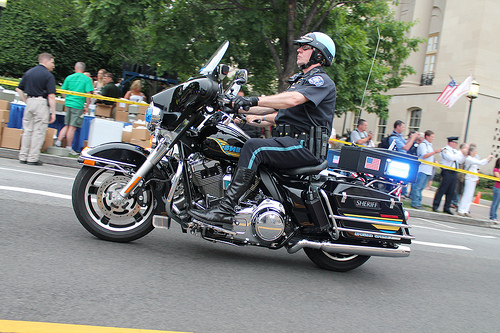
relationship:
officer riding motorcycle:
[183, 27, 343, 231] [68, 27, 416, 275]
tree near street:
[173, 2, 434, 110] [2, 153, 496, 332]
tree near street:
[1, 3, 173, 95] [2, 153, 496, 332]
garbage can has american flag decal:
[334, 140, 391, 181] [363, 155, 382, 171]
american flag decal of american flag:
[363, 155, 382, 171] [359, 153, 385, 178]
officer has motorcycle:
[183, 27, 343, 231] [68, 27, 416, 275]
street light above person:
[455, 74, 484, 144] [461, 141, 496, 221]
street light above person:
[455, 74, 484, 144] [430, 133, 472, 218]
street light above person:
[455, 74, 484, 144] [448, 138, 472, 214]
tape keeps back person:
[1, 77, 500, 201] [58, 48, 100, 160]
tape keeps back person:
[1, 77, 500, 201] [90, 64, 107, 88]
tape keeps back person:
[1, 77, 500, 201] [94, 71, 122, 111]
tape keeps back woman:
[1, 77, 500, 201] [123, 79, 147, 102]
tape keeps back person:
[1, 77, 500, 201] [343, 117, 376, 149]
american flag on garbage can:
[359, 153, 385, 178] [334, 140, 391, 181]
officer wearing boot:
[183, 27, 343, 231] [183, 164, 260, 234]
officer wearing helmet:
[183, 27, 343, 231] [291, 28, 339, 74]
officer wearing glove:
[183, 27, 343, 231] [224, 89, 262, 115]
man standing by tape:
[9, 47, 61, 171] [1, 77, 500, 201]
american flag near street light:
[433, 77, 460, 112] [455, 74, 484, 144]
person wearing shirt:
[58, 48, 100, 160] [57, 70, 96, 112]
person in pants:
[461, 141, 496, 221] [454, 175, 480, 218]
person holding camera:
[461, 141, 496, 221] [483, 151, 498, 163]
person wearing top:
[485, 154, 500, 224] [489, 163, 500, 190]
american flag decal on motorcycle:
[360, 151, 384, 175] [68, 27, 416, 275]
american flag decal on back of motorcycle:
[360, 151, 384, 175] [68, 27, 416, 275]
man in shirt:
[9, 47, 61, 171] [12, 61, 60, 99]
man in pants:
[9, 47, 61, 171] [13, 94, 55, 169]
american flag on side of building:
[433, 77, 460, 112] [328, 2, 500, 177]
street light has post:
[455, 74, 484, 144] [461, 99, 478, 146]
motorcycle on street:
[68, 27, 416, 275] [2, 153, 496, 332]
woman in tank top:
[122, 74, 150, 105] [126, 91, 146, 102]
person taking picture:
[378, 117, 420, 201] [405, 126, 424, 143]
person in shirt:
[378, 117, 420, 201] [381, 130, 410, 160]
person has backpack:
[378, 117, 420, 201] [376, 133, 403, 150]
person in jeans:
[485, 154, 500, 224] [487, 183, 500, 223]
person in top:
[485, 154, 500, 224] [489, 163, 500, 190]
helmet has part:
[291, 28, 339, 74] [290, 35, 312, 49]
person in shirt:
[58, 48, 100, 160] [57, 70, 96, 112]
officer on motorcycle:
[183, 27, 343, 231] [68, 27, 416, 275]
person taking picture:
[461, 141, 496, 221] [484, 150, 499, 167]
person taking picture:
[430, 133, 472, 218] [457, 143, 471, 160]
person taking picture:
[410, 129, 448, 216] [431, 144, 448, 159]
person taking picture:
[343, 117, 376, 149] [363, 129, 378, 145]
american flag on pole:
[433, 77, 460, 112] [445, 73, 458, 83]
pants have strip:
[232, 122, 333, 178] [246, 135, 311, 173]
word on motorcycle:
[349, 195, 387, 213] [68, 27, 416, 275]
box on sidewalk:
[1, 123, 25, 156] [2, 119, 483, 228]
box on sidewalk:
[1, 106, 10, 122] [2, 119, 483, 228]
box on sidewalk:
[0, 96, 12, 109] [2, 119, 483, 228]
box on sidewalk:
[84, 114, 129, 152] [2, 119, 483, 228]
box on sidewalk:
[93, 102, 115, 119] [2, 119, 483, 228]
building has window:
[328, 2, 500, 177] [416, 28, 444, 92]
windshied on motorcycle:
[190, 35, 234, 77] [68, 27, 416, 275]